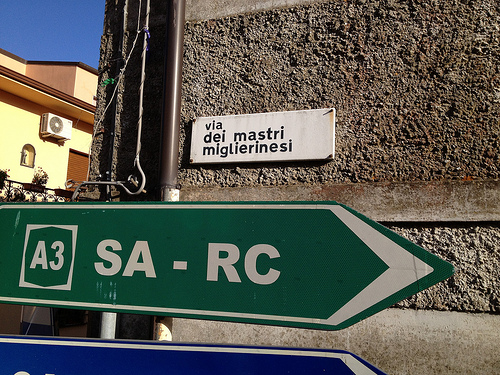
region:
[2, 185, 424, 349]
sign is green and white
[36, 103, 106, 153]
White external air conditioning unit.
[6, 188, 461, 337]
Green traffic sign pointing left.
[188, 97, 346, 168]
White sign with Italian words.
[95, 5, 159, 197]
Metal hook connecting wires.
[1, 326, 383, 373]
Blue traffic sign.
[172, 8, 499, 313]
Concrete wall with white sign.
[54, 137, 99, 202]
Wooden door with slats.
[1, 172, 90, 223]
Metal railing with plants.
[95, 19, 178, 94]
Blue and green ties on wires.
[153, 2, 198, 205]
Metal pipe.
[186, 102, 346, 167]
a small white sign with black letters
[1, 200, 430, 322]
a green directional sign with white letters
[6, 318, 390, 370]
the top of a blue directional sign with white letters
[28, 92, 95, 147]
air conditioning unit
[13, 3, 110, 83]
a really blue sky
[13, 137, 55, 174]
an in wall shelf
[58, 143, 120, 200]
part of a brown door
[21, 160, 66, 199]
a green plant in a planter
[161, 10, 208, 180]
a brown pipe on a wall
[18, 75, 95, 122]
brown trim on the building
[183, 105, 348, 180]
sign is white with black writing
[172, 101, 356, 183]
sign is white and black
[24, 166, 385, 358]
a street sign that is green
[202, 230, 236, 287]
a white letter on the sign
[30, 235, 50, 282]
a white letter on the sign